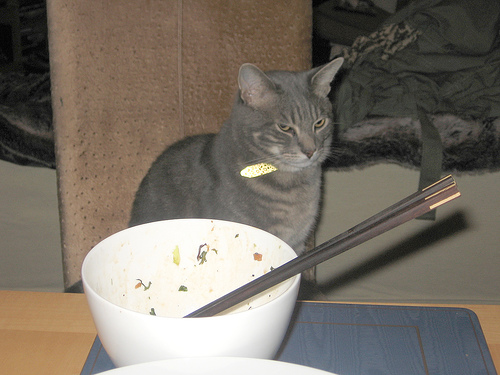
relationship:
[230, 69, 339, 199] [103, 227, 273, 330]
cat looking at bowl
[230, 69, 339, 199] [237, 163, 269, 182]
cat wearing collar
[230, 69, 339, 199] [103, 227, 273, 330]
cat near bowl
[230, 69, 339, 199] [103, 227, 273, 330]
cat next to bowl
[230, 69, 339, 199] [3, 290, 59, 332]
cat on table